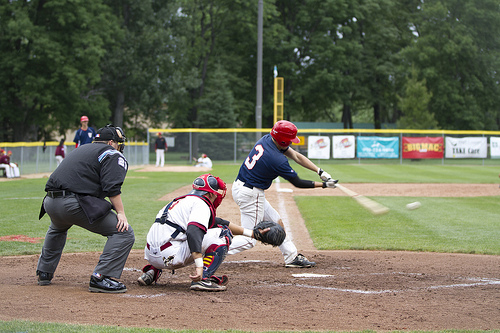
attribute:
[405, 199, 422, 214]
baseball — white, blurry looking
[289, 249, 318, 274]
shoe — black, for tennis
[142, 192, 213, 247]
shirt — white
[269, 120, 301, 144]
helmet — red, hard, baseball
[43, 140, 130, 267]
clothing — black 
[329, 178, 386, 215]
baseball bat — wood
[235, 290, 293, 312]
indention — small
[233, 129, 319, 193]
shirt — black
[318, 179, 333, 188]
hand — hitter's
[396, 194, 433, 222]
baseball — in air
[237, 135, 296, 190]
jersey — blue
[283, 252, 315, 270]
shoe — black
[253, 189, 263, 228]
stripe — red, down pant 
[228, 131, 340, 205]
shirt — blue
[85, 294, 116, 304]
indentations — small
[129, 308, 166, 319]
indentations — small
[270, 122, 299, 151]
helmet — red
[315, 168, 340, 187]
gloves — white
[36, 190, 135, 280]
pants — gray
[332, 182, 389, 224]
bat — for baseball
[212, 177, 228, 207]
mask — catcher's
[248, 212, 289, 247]
mitt — catcher's